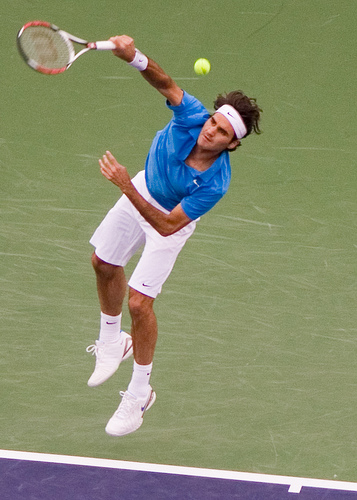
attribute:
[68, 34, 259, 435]
man — Jumping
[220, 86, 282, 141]
hair — brown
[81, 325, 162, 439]
shoes — white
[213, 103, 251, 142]
scarf — white 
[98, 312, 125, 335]
socks — white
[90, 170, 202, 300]
short — white 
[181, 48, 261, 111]
ball — yellow green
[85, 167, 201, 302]
pants — white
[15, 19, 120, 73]
tennis racket — red, white, black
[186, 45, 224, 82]
tennis ball — yellow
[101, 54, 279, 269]
shirt — white, blue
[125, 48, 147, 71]
wristband — white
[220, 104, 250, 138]
headband — black, white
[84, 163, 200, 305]
shorts — white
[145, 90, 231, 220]
t-shirt — blue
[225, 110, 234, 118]
nike logo — black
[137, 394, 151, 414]
nike logo — blue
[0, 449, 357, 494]
stripe — white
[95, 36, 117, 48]
tape — white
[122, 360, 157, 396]
sock — white 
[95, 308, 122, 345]
sock — white 